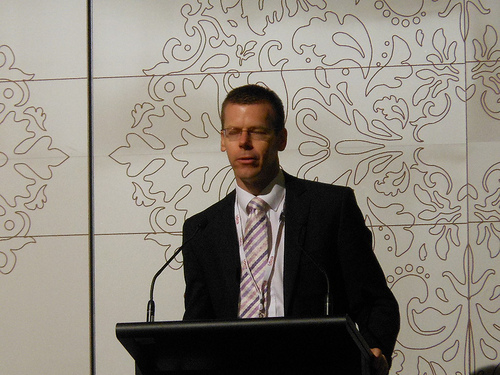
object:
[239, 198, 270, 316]
tie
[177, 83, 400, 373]
man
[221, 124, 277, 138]
glasses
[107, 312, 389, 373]
podium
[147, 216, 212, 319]
microphone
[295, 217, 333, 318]
microphone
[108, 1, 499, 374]
artwork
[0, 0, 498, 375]
wall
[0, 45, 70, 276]
artwork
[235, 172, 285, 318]
shirt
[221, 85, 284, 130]
hair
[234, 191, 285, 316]
lanyard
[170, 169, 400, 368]
jacket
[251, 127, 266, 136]
eye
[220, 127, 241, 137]
eye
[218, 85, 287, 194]
head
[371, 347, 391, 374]
hand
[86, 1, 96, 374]
separation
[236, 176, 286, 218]
neck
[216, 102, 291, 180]
face